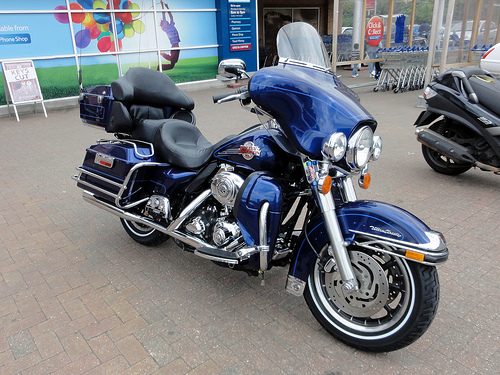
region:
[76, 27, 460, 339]
shiny blue motorcycle in foreground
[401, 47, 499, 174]
black motorcycle on right side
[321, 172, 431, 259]
orange reflectors on front of motorcycle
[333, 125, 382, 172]
front headlights of blue motorcycle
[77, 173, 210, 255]
silver tailpipe of blue motorcycle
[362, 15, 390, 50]
red and white sticker on window of store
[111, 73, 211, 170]
black seat of blue motorcycle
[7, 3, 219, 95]
advertisment in window of store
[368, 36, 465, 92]
row of shopping carts in front of store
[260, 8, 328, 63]
doors to the store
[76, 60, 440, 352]
a blue motorcyle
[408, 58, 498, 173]
a black motorcylce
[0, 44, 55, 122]
a small sign out side of the store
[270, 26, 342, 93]
a motorcyle windshield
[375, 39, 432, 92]
a large pile of some metal shoping carts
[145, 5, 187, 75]
a picture of a kid jumping and holding some ballons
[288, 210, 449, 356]
a front motorcylce tire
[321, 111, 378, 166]
a row of lights on a motorcyle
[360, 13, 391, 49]
an advertisment on a window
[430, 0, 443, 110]
a tall metal pole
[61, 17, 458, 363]
a blue motorcycle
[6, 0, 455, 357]
a blue motorcycle parked in front a building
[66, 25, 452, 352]
sit of motorcycle is black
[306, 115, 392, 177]
three headlights of motorcycle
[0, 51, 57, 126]
a sign in front of motorcycle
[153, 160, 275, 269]
engine of motorcycle is color silver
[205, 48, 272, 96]
a mirror on left side of motorcycle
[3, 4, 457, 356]
a building behind a motorcycle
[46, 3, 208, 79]
a picture of woman with balloons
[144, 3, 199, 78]
woman jumps in the air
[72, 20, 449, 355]
a shiny blue motorcycle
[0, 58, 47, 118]
a white sign with legs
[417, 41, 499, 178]
a black sidecar for motorcycle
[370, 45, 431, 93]
a row of shopping carts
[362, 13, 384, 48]
a round red sign with white letters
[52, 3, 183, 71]
a picture of a person with a lot of balloons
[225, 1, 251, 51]
a tall sign with a list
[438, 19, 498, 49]
a white car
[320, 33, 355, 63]
a row of shopping carts linked together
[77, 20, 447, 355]
a motorcycle leaning slightly to the side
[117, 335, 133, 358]
part of a road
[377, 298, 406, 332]
part of a wheel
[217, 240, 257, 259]
part of an engine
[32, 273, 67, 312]
part of a parking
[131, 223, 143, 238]
back of a bike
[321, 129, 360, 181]
light of a bike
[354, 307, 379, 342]
part of a wheel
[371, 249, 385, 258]
edge of a wheel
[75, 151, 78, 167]
part of a pavement